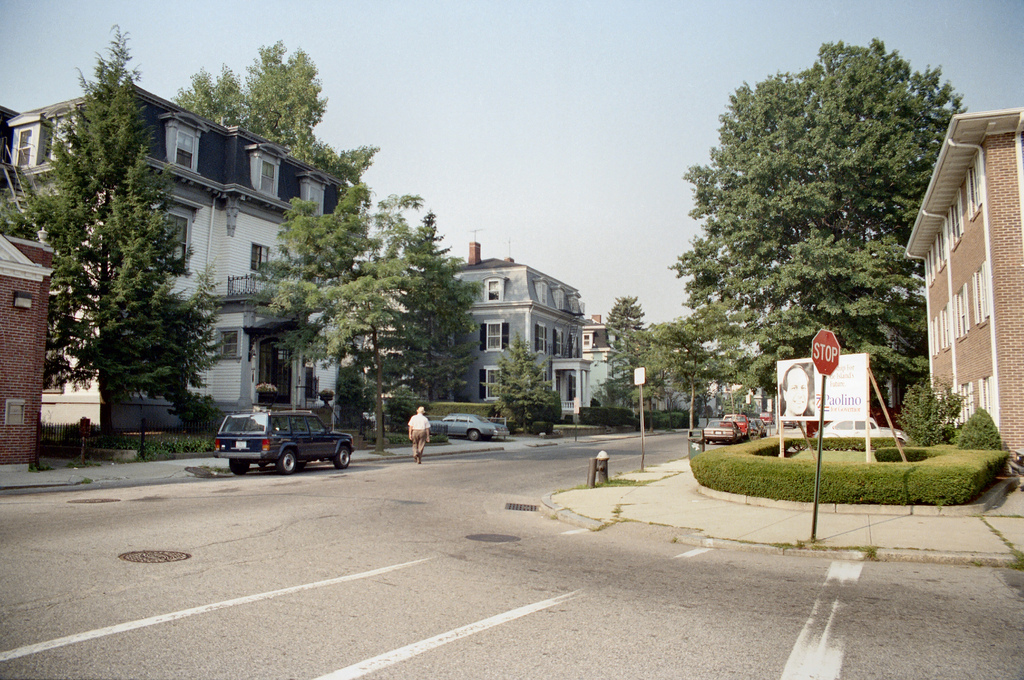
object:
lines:
[781, 559, 866, 680]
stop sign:
[811, 328, 841, 376]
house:
[440, 242, 583, 425]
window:
[250, 242, 269, 271]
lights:
[262, 439, 271, 451]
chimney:
[468, 241, 482, 265]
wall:
[0, 274, 47, 465]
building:
[0, 234, 58, 476]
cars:
[722, 415, 750, 438]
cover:
[118, 550, 192, 563]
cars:
[703, 420, 742, 444]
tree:
[255, 183, 435, 451]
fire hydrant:
[588, 450, 610, 487]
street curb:
[539, 455, 1024, 568]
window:
[484, 277, 504, 303]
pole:
[810, 375, 827, 544]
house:
[0, 83, 351, 427]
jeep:
[213, 410, 355, 475]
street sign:
[633, 367, 646, 472]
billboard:
[774, 353, 872, 421]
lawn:
[692, 436, 1012, 506]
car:
[429, 413, 511, 441]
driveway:
[447, 436, 546, 451]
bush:
[958, 408, 1001, 451]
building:
[904, 107, 1024, 489]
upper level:
[0, 85, 347, 214]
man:
[408, 406, 430, 464]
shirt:
[408, 414, 432, 429]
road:
[0, 430, 1024, 680]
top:
[595, 450, 609, 460]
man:
[778, 365, 808, 417]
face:
[786, 367, 810, 414]